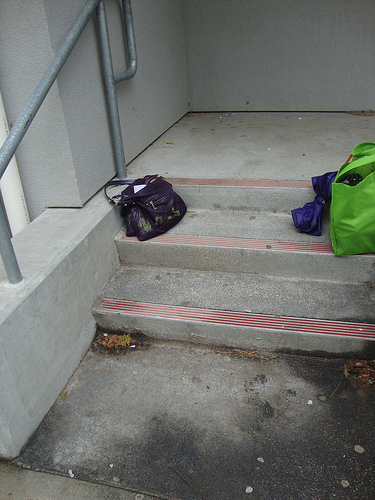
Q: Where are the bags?
A: On the stairs.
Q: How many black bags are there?
A: One.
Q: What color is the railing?
A: Gray.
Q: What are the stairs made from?
A: Concrete.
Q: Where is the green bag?
A: On the right.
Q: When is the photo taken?
A: Daytime.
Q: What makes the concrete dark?
A: It is wet.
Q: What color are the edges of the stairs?
A: Red.